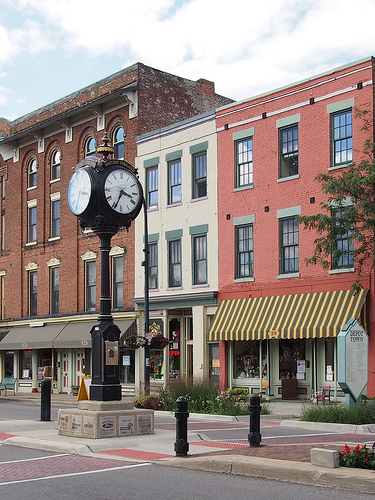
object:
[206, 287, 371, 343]
awning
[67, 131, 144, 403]
clock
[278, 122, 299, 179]
window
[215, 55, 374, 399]
building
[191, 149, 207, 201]
window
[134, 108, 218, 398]
building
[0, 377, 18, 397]
bench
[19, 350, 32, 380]
window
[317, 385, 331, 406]
chair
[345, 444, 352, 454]
flower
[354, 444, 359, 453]
flower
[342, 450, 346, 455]
flower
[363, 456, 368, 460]
flower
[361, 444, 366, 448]
flower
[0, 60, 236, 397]
building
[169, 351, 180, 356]
sign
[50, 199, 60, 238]
window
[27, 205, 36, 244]
window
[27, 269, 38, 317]
window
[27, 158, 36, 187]
window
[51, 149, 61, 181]
window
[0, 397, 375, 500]
street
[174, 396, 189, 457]
pole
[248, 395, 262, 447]
pole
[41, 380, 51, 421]
pole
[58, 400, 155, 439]
base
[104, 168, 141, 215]
clock face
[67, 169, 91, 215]
clock face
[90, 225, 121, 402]
pole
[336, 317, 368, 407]
sign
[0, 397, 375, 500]
pavement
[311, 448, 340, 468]
block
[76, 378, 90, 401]
triangle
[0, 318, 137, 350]
awning